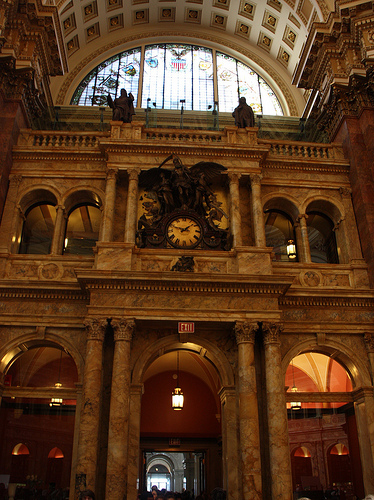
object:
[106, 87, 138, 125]
statue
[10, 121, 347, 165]
balcony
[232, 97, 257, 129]
statue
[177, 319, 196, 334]
sign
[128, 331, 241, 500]
archway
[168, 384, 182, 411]
lamp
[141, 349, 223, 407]
ceiling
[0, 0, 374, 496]
building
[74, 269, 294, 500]
entrance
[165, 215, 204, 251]
clock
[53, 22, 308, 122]
window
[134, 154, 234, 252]
statue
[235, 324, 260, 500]
column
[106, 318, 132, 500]
column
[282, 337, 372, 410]
canopy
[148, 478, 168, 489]
sunlight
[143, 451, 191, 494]
doors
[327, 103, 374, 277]
wall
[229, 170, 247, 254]
pillar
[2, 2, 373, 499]
house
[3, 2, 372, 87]
roof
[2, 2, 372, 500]
palace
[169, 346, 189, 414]
light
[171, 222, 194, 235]
hands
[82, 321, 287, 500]
columns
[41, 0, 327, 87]
ceiling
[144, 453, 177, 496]
doorway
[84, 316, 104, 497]
column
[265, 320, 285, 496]
column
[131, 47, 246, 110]
light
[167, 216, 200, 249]
numbers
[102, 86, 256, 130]
sculptures